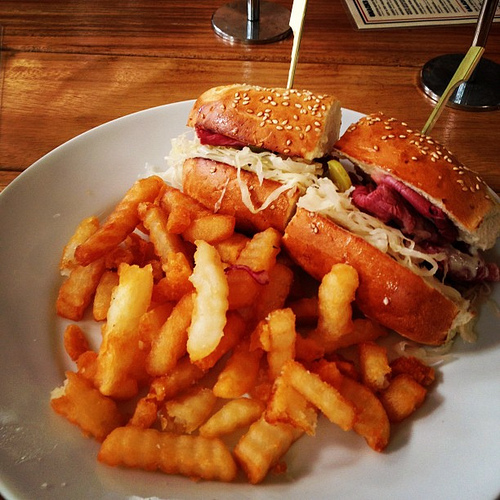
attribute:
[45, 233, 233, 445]
fries —  crinkled , Small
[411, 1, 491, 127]
stick — green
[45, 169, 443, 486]
fries — Small, crinkled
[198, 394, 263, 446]
cut fry — Small ,  crinkled 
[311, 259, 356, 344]
cut frie — Small, crinkled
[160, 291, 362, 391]
fries — crinkled, Small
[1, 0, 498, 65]
board — wood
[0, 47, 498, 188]
board — wood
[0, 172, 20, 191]
board — wood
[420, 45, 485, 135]
toothpick — green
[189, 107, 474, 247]
sandwich — reuben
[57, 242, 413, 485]
crinkled fries — Small 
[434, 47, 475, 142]
toothpick — white 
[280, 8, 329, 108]
toothpick — white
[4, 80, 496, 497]
plate — white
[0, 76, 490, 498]
sandwich — reuben